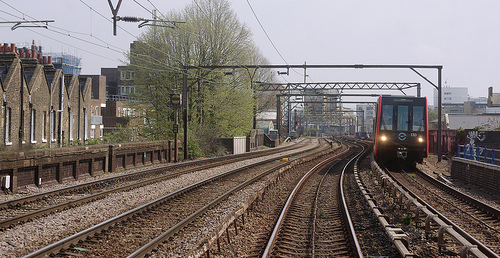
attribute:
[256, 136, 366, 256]
train track — second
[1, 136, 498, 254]
tracks — metal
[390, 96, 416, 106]
window — digital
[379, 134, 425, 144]
headlights — bright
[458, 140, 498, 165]
fence — blue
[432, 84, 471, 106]
building — large , white 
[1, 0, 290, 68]
wires — overhead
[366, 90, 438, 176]
train — track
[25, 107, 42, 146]
framed window — white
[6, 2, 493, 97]
sky — grey, overcast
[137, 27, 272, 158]
trees — green, tall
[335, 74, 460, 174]
train — red, black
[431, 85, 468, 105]
building — tall, white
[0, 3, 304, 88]
power lines — black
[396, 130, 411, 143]
logo — blue, round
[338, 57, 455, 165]
caboose — red, black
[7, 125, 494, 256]
track — second, train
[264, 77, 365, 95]
structure — metal 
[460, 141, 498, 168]
railing — blue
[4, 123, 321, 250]
track — far left